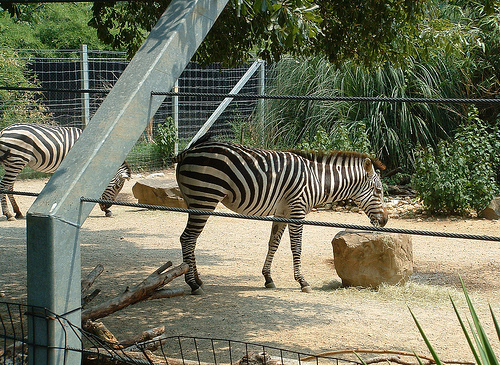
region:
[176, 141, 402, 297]
zebra in a zoo eating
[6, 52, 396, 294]
two zebras in a zoo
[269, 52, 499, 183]
foliage mimicking natural zebra habitat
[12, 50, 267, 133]
tall steel fence in zebra paddock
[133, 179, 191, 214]
large boulder in zebra enclosure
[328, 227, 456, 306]
large boulder with food for zebra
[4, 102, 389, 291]
a pair of captive zebras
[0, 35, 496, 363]
steel enclosure containing zebras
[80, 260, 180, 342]
dead wood on ground in zoo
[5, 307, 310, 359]
steel fence in need of repair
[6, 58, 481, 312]
zebras in a fenced in area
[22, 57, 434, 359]
zebras standing in dirt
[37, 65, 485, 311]
zebras eating off the ground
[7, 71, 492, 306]
two zebras in a fenced in area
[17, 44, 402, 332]
black and white zebras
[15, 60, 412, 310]
two black and white zebras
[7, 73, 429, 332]
black and white zebras in a field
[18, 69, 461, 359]
black and white zebras with their head down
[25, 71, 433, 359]
zebras in a dirt field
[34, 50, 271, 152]
fencing behind the zebras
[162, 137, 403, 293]
zebra standing next to a rock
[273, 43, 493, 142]
lush greenery and vegetation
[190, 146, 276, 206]
black and white stripes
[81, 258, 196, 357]
pieces of wood laying on the ground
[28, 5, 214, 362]
sturdy metal fencing post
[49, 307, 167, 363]
a bend in the fencing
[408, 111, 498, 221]
small green bushes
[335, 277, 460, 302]
straw or hay on the ground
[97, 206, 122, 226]
a ball that the zebra is smelling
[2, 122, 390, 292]
two zebras contained in a fenced area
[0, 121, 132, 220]
the zebra's nose touch an object on the ground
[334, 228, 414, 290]
a large rock on the ground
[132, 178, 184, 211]
a rock on the ground in front of a zebra sniffing an object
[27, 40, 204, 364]
a blue metal beam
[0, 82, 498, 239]
two wires inside the blue beam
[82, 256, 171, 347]
wooden sticks beside the fence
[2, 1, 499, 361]
the zebras' area at the zoo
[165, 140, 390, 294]
a zebra eating something on top of a rock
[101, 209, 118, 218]
an object on the ground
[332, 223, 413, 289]
large brown rock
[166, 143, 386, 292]
zebra standing over rock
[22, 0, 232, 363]
gray angled metal pole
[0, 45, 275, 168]
silver chain link fence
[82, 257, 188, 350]
logs laying on the ground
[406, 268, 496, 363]
long blades of green grass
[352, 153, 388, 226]
head of the zebra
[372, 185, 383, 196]
eye on the zebra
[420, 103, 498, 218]
large green leafy bush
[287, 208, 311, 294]
front leg of zebra